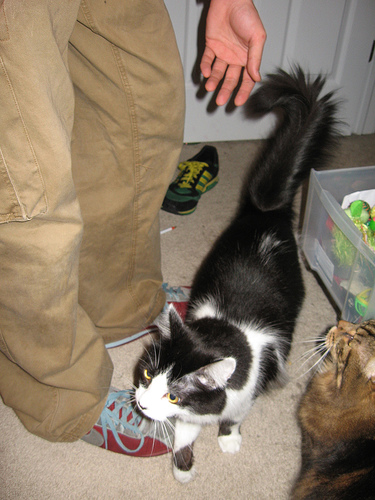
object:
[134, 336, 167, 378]
whiskers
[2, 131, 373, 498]
carpeting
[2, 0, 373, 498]
room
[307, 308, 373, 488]
cat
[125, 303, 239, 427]
face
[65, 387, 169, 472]
shoes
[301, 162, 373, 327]
drawer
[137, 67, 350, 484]
cat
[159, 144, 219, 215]
shoe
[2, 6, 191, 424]
pants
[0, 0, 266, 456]
man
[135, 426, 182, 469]
whiskers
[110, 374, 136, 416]
whiskers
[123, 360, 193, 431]
markings